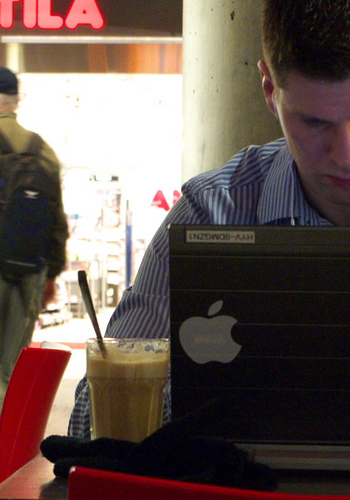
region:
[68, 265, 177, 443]
glass with a spoon in it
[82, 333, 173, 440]
glass filled with beige substance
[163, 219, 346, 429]
black apple laptop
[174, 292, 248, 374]
apple logo on laptop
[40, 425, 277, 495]
pair of black gloves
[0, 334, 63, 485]
back of red chair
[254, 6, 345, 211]
half of a person's face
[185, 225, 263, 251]
white label on apple laptop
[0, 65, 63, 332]
back of person wearing a backpack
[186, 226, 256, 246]
produt serial number sticker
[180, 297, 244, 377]
white Apple computers logo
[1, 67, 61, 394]
old man wearing backpack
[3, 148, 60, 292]
black backpack with white logo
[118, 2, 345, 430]
man using a black laptop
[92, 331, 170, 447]
mixed coffee drink in clear glass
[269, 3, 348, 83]
a man's short brown hair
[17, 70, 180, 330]
over-lit entrance to a store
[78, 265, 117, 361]
black plastic stirring spoon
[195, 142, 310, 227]
blue and white collared shirt with vertical stripes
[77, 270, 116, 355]
part of a silverware handle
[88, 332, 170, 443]
a tall glass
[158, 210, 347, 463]
part of a laptop computer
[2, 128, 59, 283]
a large black backpack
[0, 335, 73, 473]
part of a red chair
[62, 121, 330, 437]
part of a man's long sleeve shirt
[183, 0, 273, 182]
part of a large white pole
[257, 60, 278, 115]
the ear of a man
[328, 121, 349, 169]
the nose of a man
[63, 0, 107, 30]
part of a capital red letter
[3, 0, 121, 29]
capitalized red letter above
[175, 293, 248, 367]
apple computer log on laptop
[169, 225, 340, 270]
laptop with letter on top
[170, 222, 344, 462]
a black apple laptop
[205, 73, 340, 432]
man looking at his laptop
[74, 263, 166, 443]
a drink in a glass cup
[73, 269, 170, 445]
yellow colored beverage in cup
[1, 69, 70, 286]
man with black back pack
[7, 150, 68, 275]
a black back pack with lettering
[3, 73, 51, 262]
a person wearing a black cap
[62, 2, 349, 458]
man looking at computer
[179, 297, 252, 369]
apple logo on computer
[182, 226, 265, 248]
white label on computer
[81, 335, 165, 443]
brown liquid in the cup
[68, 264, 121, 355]
spoon in the cup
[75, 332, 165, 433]
cup made of glass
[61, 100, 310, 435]
man's shirt is striped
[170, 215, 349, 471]
the computer is black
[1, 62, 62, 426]
man wearing a backpack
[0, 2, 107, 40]
red letters on sign